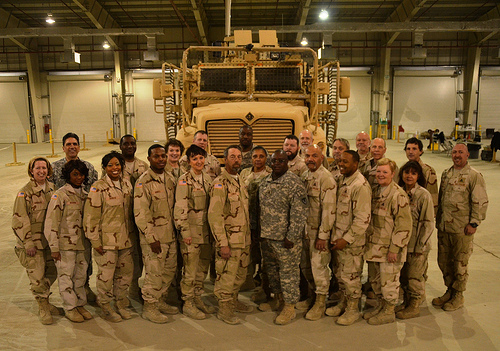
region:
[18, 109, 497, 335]
a large group of men and women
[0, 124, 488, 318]
men and women in uniform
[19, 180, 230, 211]
American flag patches on shoulders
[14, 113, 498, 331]
a group of military personnel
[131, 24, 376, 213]
a military vehicle behind people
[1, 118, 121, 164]
yellow poles with chain going through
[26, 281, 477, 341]
tan boots on thier feet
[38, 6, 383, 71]
four lights from the ceiling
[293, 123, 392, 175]
a few bald headed men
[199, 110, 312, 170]
grill on front of vehicle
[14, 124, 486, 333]
row of soldiers in cammo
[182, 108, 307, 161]
grate of the front of a truck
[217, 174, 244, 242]
camoflauge on a soldier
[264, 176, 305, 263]
camoflauge on a soldier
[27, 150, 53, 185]
smiling face of a woman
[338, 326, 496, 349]
reflection of the soldiers on the floor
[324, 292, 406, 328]
brown boots of soldiers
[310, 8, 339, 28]
white light on the ceiling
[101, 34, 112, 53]
white light on the ceiling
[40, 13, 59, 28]
white light on a ceiling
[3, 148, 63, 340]
PErson standing on the ground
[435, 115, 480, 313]
PErson standing on the ground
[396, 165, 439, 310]
PErson standing on the ground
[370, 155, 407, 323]
PErson standing on the ground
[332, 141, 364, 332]
PErson standing on the ground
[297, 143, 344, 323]
PErson standing on the ground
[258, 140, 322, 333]
PErson standing on the ground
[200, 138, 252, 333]
PErson standing on the ground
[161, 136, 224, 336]
PErson standing on the ground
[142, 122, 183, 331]
PErson standing on the ground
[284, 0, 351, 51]
the lights are on the ceiling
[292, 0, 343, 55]
the lights are on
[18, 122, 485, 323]
soldiers are standing together to take the picture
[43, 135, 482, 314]
the uniforms are camouflage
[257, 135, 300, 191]
the man in the center is wearing glasses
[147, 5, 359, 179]
a truck is parked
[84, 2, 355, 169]
the truck is behind the people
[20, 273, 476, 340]
everyone is wearing boots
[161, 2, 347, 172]
the truck is tan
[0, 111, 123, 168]
the poles are yellow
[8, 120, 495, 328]
soldiers posing for a photo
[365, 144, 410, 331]
the woman is blonde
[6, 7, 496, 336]
a truck behind soldiers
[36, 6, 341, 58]
lights on the ceiling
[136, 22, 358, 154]
truck is color yellow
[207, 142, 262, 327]
man has a beard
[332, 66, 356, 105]
mirror on right side of truck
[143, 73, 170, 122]
mirror on left side of truck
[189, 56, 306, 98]
wipes on the windshield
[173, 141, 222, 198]
woman has black hair